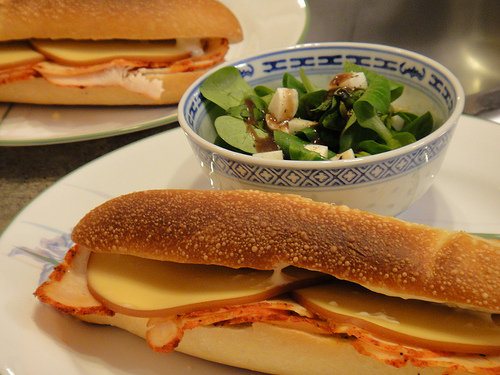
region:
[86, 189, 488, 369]
A turkey sandwich on the plate.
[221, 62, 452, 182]
A bowl of salad.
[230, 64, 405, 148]
green leaves in the bowl.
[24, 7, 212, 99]
A sandwich on the plate.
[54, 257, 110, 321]
Turkey meat on the sandwich.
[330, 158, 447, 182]
The bowl has a blue design around the edge.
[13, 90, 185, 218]
The plate is round.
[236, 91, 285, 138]
A brown dressing on the salad.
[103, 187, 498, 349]
A hoagie roll on the sandwich.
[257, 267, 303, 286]
Mayo on the bread.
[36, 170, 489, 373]
TOASTED DELI PREPARED SANDWICH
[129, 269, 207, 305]
FRESH DELI SLICED MEAT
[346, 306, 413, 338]
PART OF DELI MEAT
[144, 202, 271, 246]
PART OF TOASTED DELI BUN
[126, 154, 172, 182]
PART OF WHITE SERVING PLATE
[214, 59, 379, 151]
PART OF FRESH GREEN SALAD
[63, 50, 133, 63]
PART OF FRESH DELI MEAT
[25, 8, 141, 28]
PART OF TOASTED DELI BUN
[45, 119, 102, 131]
PART OF GREEN RIMMED PLATE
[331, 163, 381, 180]
PART OF DECORATION ON BOWL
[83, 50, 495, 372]
food on a plate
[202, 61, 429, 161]
salad in a bowl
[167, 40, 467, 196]
bowl on a plate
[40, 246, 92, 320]
meat on a sandwich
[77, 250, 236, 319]
cheese on a sandwich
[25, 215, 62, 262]
flower on a plate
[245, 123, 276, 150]
dressing on a salad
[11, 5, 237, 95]
sandwich on a plate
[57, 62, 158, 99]
meat on a sandwich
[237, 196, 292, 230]
seeds on the bread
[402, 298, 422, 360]
There is a piece of cheese here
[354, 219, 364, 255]
There is some brown bread here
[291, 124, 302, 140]
There is a salad that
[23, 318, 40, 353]
There is a white plate that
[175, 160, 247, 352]
Jackson Mingus took this photo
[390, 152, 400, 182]
There is a blue design on this bowl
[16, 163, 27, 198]
There is a brown countertop here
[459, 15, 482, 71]
There is a stainless steel piece here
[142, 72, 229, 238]
Jackson Mingus took this photo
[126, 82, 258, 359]
This photo has a great deal of detail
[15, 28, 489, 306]
this is a lunch meal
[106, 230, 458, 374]
this is a sub sandwich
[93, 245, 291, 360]
the sandwich has lunch meat and cheese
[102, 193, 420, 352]
the bread is brown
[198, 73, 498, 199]
this is a small salad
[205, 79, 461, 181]
the salad is green and white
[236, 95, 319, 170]
the dressing is brown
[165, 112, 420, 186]
the bowl is blue and white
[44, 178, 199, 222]
the plate is white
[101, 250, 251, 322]
the cheese is light yellow